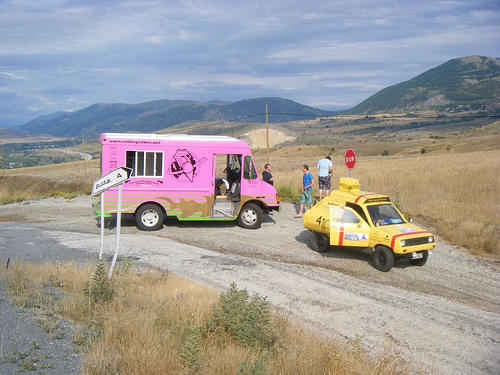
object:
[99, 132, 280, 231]
truck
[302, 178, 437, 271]
delivery car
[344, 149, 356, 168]
sign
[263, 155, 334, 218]
men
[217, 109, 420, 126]
power line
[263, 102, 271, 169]
pole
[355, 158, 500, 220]
grass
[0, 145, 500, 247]
field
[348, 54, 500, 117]
mountain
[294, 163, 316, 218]
man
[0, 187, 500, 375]
road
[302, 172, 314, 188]
shirt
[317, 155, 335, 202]
man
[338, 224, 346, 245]
red stripes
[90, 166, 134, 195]
sign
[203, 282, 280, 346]
shrub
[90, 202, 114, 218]
green bumper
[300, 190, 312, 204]
green shorts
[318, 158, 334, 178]
light blue shirt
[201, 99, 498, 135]
wires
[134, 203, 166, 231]
tire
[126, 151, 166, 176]
window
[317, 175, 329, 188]
shorts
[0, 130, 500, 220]
sky